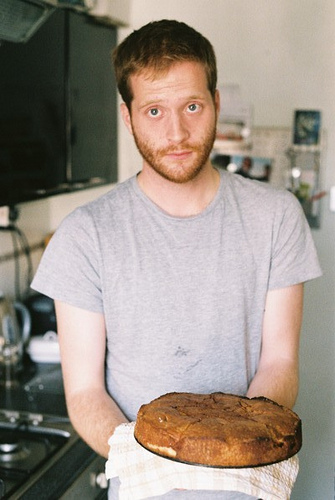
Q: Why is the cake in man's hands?
A: To take a picture.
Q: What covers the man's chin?
A: Beard.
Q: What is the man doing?
A: Looking at the camera.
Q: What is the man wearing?
A: A shirt.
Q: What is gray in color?
A: The shirt.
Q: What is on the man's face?
A: Beard.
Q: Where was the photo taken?
A: In a room.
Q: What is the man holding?
A: Food.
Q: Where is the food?
A: In man's hands.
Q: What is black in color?
A: The cabinet.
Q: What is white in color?
A: The wall.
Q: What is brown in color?
A: The food.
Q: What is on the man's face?
A: A beard.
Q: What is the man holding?
A: A cake.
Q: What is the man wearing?
A: A grey shirt.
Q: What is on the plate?
A: A cake.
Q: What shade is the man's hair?
A: Red.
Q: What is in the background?
A: A black cabinet.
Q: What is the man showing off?
A: A cake.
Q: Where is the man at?
A: In the kitchen.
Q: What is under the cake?
A: A white kitchen towel.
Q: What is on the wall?
A: Blurry pictures.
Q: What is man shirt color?
A: Grey.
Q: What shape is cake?
A: Round.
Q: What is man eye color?
A: Green.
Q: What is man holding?
A: Cake.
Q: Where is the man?
A: Kitchen.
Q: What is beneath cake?
A: Towel.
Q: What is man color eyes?
A: Green.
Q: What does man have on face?
A: Facial hair.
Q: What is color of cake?
A: Brown.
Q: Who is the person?
A: A man.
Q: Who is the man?
A: A chef.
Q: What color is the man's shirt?
A: Gray.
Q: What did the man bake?
A: Bread.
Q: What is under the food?
A: Towel.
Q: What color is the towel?
A: White and yellow.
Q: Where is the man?
A: In the kitchen.